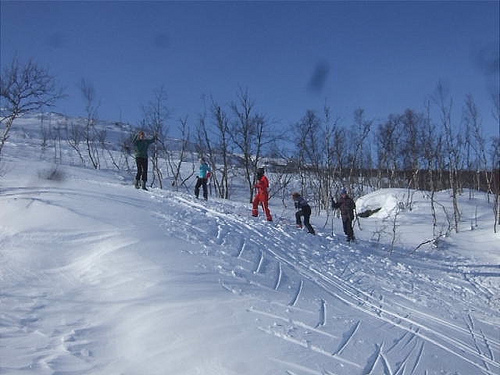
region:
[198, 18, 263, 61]
Clear weather conditions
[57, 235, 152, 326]
Snow on the ground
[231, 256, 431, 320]
Ski tracks in the snow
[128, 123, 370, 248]
Five people cross-country skiing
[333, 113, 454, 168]
Trees don't have leaves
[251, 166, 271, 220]
Person in a red snow suit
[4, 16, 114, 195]
Photo taken in the daytime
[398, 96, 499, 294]
Photo taken in the winter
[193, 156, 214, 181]
Girl in a light blue coat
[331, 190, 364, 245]
Man in a black snow suit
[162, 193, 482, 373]
Tracks in the snow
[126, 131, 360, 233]
People standing on the snowy hill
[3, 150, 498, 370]
Snow on the hill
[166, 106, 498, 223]
Bare trees behind the people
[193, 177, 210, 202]
This person is wearing black pants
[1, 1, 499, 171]
Blue sky above the hill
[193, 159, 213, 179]
This person has a blue jacket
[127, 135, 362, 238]
Five people standing in the snow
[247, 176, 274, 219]
This person is wearing red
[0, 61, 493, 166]
Bare trees behind the people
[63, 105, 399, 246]
group of people in the snow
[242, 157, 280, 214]
person wearing all red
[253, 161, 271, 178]
black snow cap on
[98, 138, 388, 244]
people hiking up snowy mountain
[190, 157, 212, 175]
person wearing blue snow jacket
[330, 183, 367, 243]
person wearing grey snow jacket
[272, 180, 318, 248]
person taking a step up the mountain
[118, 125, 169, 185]
person with arms going up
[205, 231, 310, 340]
marks in the snow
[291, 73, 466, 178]
trees with no leaves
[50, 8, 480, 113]
clear blue sky overhead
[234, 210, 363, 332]
tracks in the snow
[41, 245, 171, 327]
icy white snow on the ground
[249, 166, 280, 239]
person wearing red snowsuit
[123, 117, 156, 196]
a woman wearing a green jacket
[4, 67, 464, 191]
bare trees behind the people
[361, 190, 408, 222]
small hill of snow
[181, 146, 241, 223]
a person wearing a light blue jacket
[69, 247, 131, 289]
sunlight reflecting on the snow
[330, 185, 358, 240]
a person wearing a blacks snowsuit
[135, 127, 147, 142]
the head of a man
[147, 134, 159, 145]
the arm of a man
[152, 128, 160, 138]
the hand of a man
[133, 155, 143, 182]
the leg of a man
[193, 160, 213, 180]
a blue coat on the person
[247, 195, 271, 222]
a pair of red pants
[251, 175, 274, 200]
a red coat on the person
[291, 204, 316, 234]
a pair of black pants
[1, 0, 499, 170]
a clear blue sky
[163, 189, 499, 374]
tracks in the snow